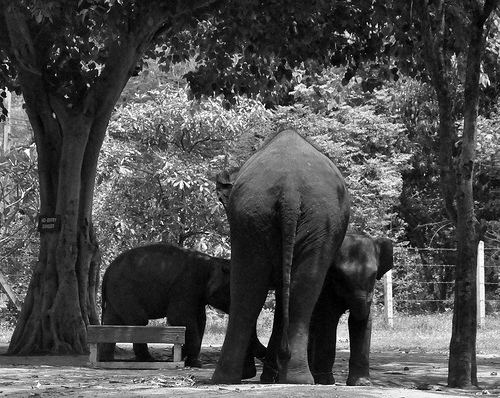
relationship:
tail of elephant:
[268, 195, 307, 324] [219, 124, 356, 385]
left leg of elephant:
[216, 255, 270, 370] [219, 130, 363, 332]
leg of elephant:
[280, 260, 330, 386] [219, 130, 363, 332]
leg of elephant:
[259, 281, 289, 382] [219, 130, 363, 332]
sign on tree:
[35, 214, 62, 233] [9, 39, 123, 355]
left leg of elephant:
[209, 253, 274, 386] [213, 128, 349, 386]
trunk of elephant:
[345, 280, 384, 347] [219, 137, 384, 381]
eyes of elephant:
[336, 267, 392, 285] [293, 226, 398, 389]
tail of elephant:
[100, 270, 107, 326] [100, 246, 268, 367]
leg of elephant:
[121, 317, 155, 359] [100, 246, 268, 367]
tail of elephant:
[281, 195, 301, 349] [213, 128, 349, 386]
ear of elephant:
[373, 228, 398, 281] [302, 229, 402, 388]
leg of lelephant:
[309, 307, 343, 384] [306, 217, 400, 386]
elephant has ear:
[319, 229, 403, 382] [374, 234, 394, 279]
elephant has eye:
[307, 232, 392, 384] [370, 270, 377, 279]